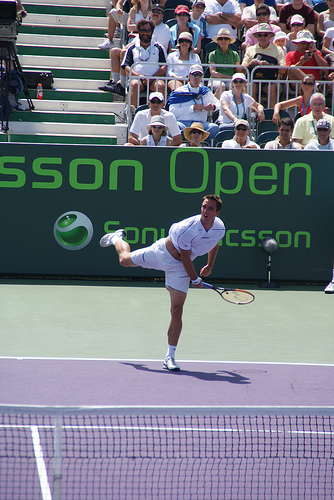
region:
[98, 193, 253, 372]
tennis player on court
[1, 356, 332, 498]
purple tennis court with white lines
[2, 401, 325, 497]
tennis net with white tape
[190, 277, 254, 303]
tennis racket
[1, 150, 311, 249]
advertisements on the wall of tennis court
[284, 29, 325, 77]
man in red shirt looking at his phone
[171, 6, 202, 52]
woman in red hat with a blue sweater over her shoulders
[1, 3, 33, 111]
television camera on the steps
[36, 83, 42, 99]
bottle of sports drink on the steps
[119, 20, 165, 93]
man with beard and sunglasses sitting on the aisle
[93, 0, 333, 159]
Spectators in the stands on a warm day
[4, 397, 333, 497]
Tennis net with white edging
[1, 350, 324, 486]
White lines on a grey tennis court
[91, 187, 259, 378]
Male tennis player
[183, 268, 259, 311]
Tennis racket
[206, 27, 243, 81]
Person in sun glasses and a green shirt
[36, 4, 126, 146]
Green and white bleacher steps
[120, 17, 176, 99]
Large man with wild hair and a bushy beard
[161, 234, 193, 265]
A bit of the belly showing between shorts and pants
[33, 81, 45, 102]
Drink bottle sitting on the stairs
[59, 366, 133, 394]
Purple colored tennis court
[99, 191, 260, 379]
Man playing tennis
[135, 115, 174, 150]
Woman in tennis stands wearing hat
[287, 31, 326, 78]
Man in the stands playing with his camera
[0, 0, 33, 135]
TV camera behind tennis court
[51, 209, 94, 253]
SonyEricsson logo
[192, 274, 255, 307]
Tennis racket with letter "P" on it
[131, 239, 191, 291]
White tennis shorts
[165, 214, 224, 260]
White tennis shirt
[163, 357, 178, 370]
White tennis shoes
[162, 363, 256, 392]
shadow of the player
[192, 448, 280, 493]
mesh of the net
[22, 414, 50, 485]
foul line on court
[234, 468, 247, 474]
square of the mesh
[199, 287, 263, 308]
head of the racquet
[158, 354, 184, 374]
foot of the player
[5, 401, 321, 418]
top of the net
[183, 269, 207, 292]
sweatband on man's wrist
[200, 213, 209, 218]
teeth in man's mouth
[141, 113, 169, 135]
hat on woman's head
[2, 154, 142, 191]
half of the name of the tournament in green letters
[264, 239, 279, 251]
tennis ball flying in the air.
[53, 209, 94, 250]
green and lavender logo of the tournament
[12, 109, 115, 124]
one of the green stair rises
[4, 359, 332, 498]
lavender tennis court with net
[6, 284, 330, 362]
green outside the boundary lines of the tennis court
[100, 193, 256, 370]
tennis player in white returning the ball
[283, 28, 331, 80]
a spectator in red talking on the phone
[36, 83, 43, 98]
someone's bottle with an orange label on the stairs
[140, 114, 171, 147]
spectator in front wearing white